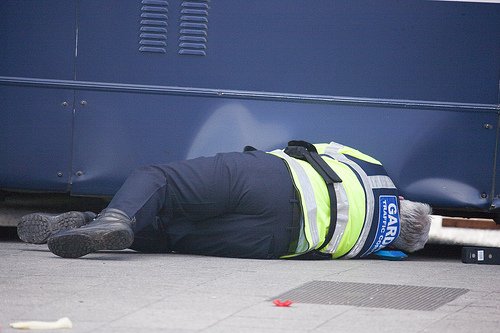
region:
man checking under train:
[22, 95, 495, 285]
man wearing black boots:
[8, 197, 143, 279]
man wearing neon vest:
[276, 128, 376, 258]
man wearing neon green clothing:
[274, 134, 388, 269]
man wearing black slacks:
[113, 140, 310, 268]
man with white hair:
[396, 185, 446, 262]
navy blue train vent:
[121, 0, 221, 66]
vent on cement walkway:
[271, 250, 474, 312]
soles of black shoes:
[13, 216, 137, 260]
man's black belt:
[289, 182, 305, 260]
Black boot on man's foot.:
[46, 213, 145, 255]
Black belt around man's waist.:
[301, 137, 340, 256]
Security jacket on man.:
[268, 133, 410, 262]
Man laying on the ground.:
[28, 133, 436, 269]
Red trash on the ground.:
[272, 295, 296, 307]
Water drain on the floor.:
[279, 273, 476, 332]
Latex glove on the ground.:
[5, 315, 84, 327]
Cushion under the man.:
[379, 245, 409, 260]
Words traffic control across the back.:
[376, 195, 388, 262]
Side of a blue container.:
[134, 0, 223, 98]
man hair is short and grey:
[402, 213, 421, 243]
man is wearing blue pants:
[223, 179, 263, 200]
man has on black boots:
[98, 211, 122, 243]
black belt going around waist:
[311, 156, 328, 187]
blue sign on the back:
[381, 194, 396, 245]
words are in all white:
[385, 203, 394, 236]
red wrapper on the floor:
[275, 292, 290, 310]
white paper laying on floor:
[10, 308, 75, 331]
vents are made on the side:
[179, 6, 192, 50]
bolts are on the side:
[79, 98, 85, 107]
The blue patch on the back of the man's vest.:
[376, 187, 396, 259]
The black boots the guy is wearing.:
[15, 210, 133, 259]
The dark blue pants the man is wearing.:
[112, 158, 292, 255]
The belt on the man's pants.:
[288, 187, 299, 252]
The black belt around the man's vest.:
[282, 138, 344, 245]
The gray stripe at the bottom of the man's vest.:
[292, 140, 313, 253]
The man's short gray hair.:
[392, 193, 429, 248]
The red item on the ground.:
[268, 298, 302, 310]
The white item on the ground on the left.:
[7, 317, 77, 332]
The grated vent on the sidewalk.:
[274, 281, 470, 309]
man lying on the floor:
[11, 134, 441, 266]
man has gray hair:
[356, 157, 435, 271]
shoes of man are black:
[14, 186, 139, 276]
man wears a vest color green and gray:
[271, 128, 405, 265]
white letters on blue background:
[371, 190, 403, 261]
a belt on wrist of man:
[282, 126, 344, 259]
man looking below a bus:
[8, 5, 498, 274]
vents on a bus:
[129, 3, 214, 63]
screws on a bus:
[51, 93, 96, 187]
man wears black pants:
[25, 123, 438, 277]